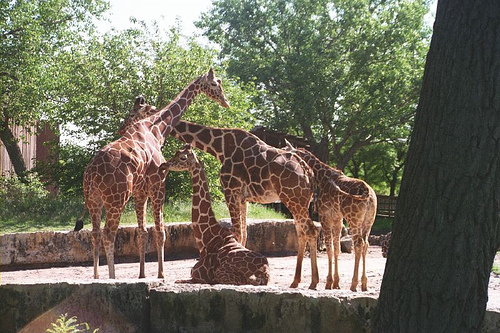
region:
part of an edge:
[216, 279, 236, 289]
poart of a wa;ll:
[221, 285, 243, 322]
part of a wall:
[256, 206, 288, 244]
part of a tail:
[231, 250, 249, 291]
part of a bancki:
[229, 225, 260, 295]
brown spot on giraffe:
[173, 122, 187, 134]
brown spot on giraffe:
[195, 129, 210, 144]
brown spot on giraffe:
[211, 137, 224, 152]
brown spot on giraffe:
[220, 132, 234, 157]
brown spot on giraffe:
[230, 147, 242, 162]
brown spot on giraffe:
[230, 163, 250, 185]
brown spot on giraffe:
[249, 166, 259, 183]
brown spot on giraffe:
[243, 157, 253, 170]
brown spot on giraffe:
[242, 148, 251, 158]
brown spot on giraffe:
[278, 172, 298, 190]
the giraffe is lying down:
[161, 142, 270, 284]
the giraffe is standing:
[59, 69, 227, 278]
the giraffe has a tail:
[63, 170, 99, 235]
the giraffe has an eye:
[208, 77, 217, 89]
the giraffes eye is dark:
[173, 151, 189, 164]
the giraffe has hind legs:
[348, 227, 374, 294]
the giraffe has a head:
[191, 66, 232, 111]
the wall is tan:
[37, 235, 65, 262]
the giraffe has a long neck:
[158, 85, 202, 135]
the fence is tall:
[24, 117, 67, 194]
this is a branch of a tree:
[78, 67, 265, 287]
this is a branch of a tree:
[157, 133, 265, 319]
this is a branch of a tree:
[169, 103, 346, 285]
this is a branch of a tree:
[271, 122, 387, 287]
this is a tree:
[41, 32, 191, 219]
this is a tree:
[222, 5, 349, 190]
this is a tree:
[334, 15, 393, 187]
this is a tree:
[343, 120, 376, 212]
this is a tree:
[372, 131, 399, 209]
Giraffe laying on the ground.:
[165, 145, 272, 285]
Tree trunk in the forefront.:
[370, 0, 499, 331]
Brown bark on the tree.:
[367, 4, 494, 329]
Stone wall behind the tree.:
[0, 262, 498, 332]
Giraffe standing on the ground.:
[61, 61, 235, 275]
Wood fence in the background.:
[0, 105, 70, 210]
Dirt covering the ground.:
[2, 233, 439, 289]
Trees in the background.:
[2, 0, 434, 207]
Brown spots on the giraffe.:
[160, 143, 272, 283]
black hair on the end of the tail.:
[68, 169, 95, 238]